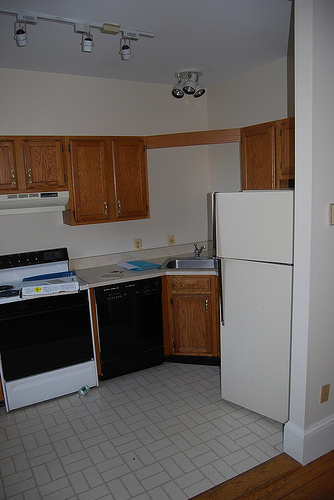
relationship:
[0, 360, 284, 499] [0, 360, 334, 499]
tiles on floor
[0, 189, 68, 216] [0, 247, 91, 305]
exhaust fan above stove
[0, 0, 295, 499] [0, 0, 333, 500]
kitchen part of house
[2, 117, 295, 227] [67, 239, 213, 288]
cabinets above countertop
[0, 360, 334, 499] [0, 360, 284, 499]
floor made of tiles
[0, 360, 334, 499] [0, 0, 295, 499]
floor part of kitchen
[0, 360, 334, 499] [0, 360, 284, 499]
floor covered in lineoleum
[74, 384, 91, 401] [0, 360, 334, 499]
bottle on top of floor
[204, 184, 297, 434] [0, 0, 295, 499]
refrigerator in kitchen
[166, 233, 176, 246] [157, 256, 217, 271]
light switch above sink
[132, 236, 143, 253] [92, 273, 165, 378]
outlet above dishwasher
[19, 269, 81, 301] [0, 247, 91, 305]
pizza box on top of stove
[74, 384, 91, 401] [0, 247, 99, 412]
bottle in front of stove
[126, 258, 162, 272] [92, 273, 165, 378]
book above dishwasher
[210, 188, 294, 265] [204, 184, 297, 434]
freezer door on front of refrigerator